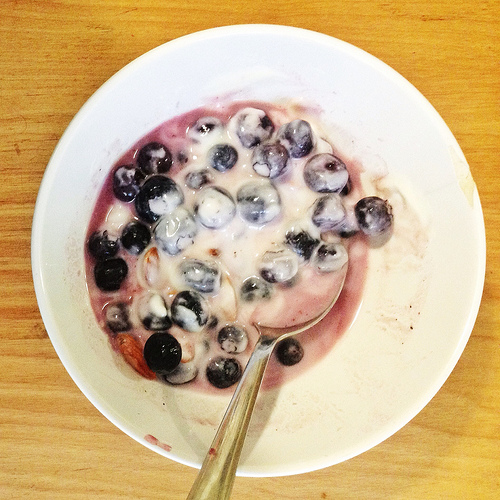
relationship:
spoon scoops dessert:
[186, 239, 347, 497] [80, 97, 398, 401]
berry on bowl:
[236, 105, 274, 146] [20, 21, 489, 483]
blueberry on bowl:
[306, 155, 348, 190] [20, 21, 489, 483]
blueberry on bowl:
[354, 195, 390, 240] [20, 21, 489, 483]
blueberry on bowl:
[237, 180, 281, 223] [20, 21, 489, 483]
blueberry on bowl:
[134, 140, 170, 174] [20, 21, 489, 483]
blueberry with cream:
[306, 155, 348, 190] [356, 170, 420, 358]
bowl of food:
[20, 21, 489, 483] [96, 119, 396, 372]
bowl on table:
[20, 21, 489, 483] [6, 4, 493, 494]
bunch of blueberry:
[85, 110, 391, 389] [88, 106, 395, 388]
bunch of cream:
[85, 110, 391, 389] [102, 105, 353, 388]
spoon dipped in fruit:
[186, 239, 347, 497] [353, 196, 390, 238]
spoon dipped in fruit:
[186, 239, 347, 497] [304, 152, 347, 197]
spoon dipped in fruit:
[186, 239, 347, 497] [246, 142, 291, 179]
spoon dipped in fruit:
[186, 239, 347, 497] [277, 119, 315, 153]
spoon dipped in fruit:
[186, 239, 347, 497] [196, 189, 233, 229]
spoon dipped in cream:
[186, 239, 347, 497] [89, 97, 429, 417]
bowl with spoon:
[20, 21, 489, 483] [186, 239, 347, 497]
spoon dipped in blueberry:
[186, 239, 347, 497] [137, 174, 182, 218]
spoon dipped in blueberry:
[186, 239, 347, 497] [237, 103, 276, 150]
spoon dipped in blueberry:
[186, 239, 347, 497] [141, 329, 190, 371]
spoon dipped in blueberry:
[186, 239, 347, 497] [304, 150, 348, 193]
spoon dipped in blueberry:
[186, 239, 347, 497] [272, 334, 311, 363]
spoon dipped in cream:
[186, 239, 347, 497] [349, 147, 430, 348]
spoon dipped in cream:
[186, 239, 347, 497] [190, 170, 311, 276]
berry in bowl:
[143, 330, 185, 381] [20, 21, 489, 483]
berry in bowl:
[113, 163, 143, 205] [20, 21, 489, 483]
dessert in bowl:
[67, 90, 443, 446] [74, 37, 484, 417]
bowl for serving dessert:
[59, 41, 484, 481] [86, 97, 428, 439]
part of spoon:
[183, 376, 263, 498] [182, 241, 374, 498]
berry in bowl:
[352, 193, 398, 243] [20, 21, 489, 483]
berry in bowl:
[225, 105, 280, 151] [20, 21, 489, 483]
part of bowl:
[45, 277, 85, 340] [20, 21, 489, 483]